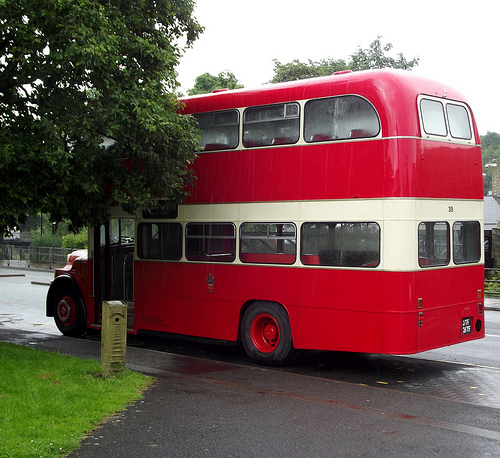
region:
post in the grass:
[93, 285, 125, 380]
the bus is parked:
[162, 125, 459, 382]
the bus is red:
[99, 152, 481, 374]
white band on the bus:
[193, 205, 469, 266]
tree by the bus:
[14, 18, 236, 228]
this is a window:
[300, 205, 382, 272]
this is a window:
[182, 216, 242, 266]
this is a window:
[230, 217, 305, 276]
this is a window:
[179, 109, 247, 154]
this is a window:
[297, 94, 389, 144]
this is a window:
[412, 210, 454, 273]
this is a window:
[446, 215, 487, 265]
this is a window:
[442, 89, 479, 146]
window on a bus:
[408, 223, 453, 263]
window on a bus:
[455, 210, 485, 275]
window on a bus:
[410, 91, 445, 131]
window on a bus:
[445, 101, 475, 137]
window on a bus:
[236, 217, 301, 268]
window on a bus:
[180, 221, 235, 261]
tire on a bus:
[205, 283, 297, 353]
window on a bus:
[240, 102, 308, 147]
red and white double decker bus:
[45, 80, 491, 357]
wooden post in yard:
[100, 299, 141, 377]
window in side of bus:
[301, 213, 387, 278]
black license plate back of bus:
[453, 309, 480, 340]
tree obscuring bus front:
[62, 71, 222, 242]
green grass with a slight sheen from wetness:
[22, 353, 87, 420]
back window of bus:
[411, 86, 478, 146]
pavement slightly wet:
[201, 373, 341, 443]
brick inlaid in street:
[450, 367, 495, 407]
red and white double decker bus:
[46, 68, 483, 366]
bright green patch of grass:
[0, 339, 158, 456]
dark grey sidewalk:
[0, 327, 499, 457]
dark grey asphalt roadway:
[0, 266, 497, 406]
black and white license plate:
[458, 315, 472, 332]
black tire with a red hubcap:
[240, 300, 291, 364]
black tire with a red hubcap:
[50, 280, 88, 340]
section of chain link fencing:
[0, 243, 80, 268]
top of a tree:
[0, 0, 205, 234]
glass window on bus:
[186, 108, 239, 145]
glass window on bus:
[244, 106, 283, 119]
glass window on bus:
[302, 100, 377, 138]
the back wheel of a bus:
[231, 305, 303, 377]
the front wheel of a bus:
[38, 275, 82, 333]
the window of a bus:
[197, 171, 385, 302]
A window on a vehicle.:
[295, 215, 384, 269]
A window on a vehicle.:
[234, 222, 298, 266]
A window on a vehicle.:
[183, 217, 238, 264]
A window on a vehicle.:
[132, 220, 182, 259]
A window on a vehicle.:
[416, 221, 451, 266]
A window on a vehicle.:
[453, 219, 482, 266]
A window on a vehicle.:
[418, 97, 445, 134]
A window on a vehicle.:
[444, 100, 470, 137]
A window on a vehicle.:
[304, 99, 377, 142]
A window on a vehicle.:
[240, 105, 301, 145]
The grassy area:
[1, 330, 179, 453]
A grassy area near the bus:
[3, 330, 158, 440]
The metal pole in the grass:
[83, 285, 159, 372]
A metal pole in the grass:
[93, 300, 149, 375]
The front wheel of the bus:
[47, 290, 85, 336]